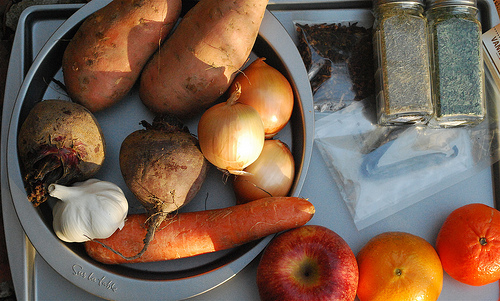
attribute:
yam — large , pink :
[121, 84, 209, 271]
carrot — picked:
[163, 196, 314, 256]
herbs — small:
[286, 15, 374, 111]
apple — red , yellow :
[256, 224, 358, 298]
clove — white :
[43, 172, 130, 249]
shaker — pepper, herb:
[372, 1, 489, 130]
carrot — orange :
[95, 206, 309, 263]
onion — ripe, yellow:
[232, 59, 295, 134]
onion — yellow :
[208, 102, 265, 177]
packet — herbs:
[296, 21, 371, 138]